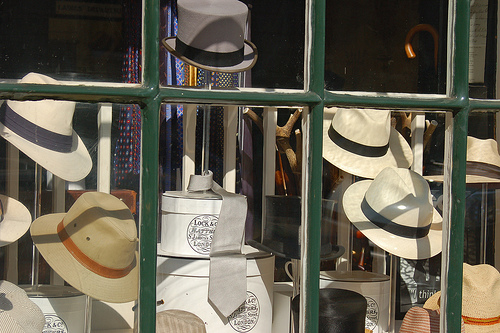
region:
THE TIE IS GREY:
[183, 162, 259, 318]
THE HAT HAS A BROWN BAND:
[20, 188, 165, 319]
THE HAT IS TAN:
[23, 183, 158, 315]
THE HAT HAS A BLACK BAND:
[337, 157, 444, 282]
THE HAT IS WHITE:
[332, 163, 447, 273]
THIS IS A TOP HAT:
[160, 2, 267, 74]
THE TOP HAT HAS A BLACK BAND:
[161, 0, 269, 81]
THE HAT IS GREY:
[161, 0, 262, 76]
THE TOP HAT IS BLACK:
[282, 281, 373, 331]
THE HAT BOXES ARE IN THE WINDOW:
[2, 186, 392, 331]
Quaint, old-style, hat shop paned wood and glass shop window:
[3, 0, 497, 330]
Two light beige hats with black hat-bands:
[323, 105, 442, 259]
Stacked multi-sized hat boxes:
[161, 188, 281, 332]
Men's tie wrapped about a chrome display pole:
[186, 168, 248, 320]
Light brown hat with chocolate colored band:
[28, 188, 140, 304]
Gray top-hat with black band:
[165, 0, 260, 73]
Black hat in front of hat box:
[320, 263, 392, 331]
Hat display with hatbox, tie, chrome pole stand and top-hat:
[163, 0, 261, 259]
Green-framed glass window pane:
[135, 84, 323, 331]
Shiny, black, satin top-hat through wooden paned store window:
[246, 190, 348, 266]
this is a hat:
[346, 162, 455, 232]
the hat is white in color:
[352, 182, 435, 234]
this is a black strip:
[331, 135, 373, 153]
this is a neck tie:
[203, 165, 247, 303]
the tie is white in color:
[223, 203, 245, 271]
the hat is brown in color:
[71, 200, 129, 248]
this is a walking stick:
[407, 19, 452, 66]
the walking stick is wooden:
[399, 23, 429, 55]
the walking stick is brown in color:
[400, 18, 427, 55]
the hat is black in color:
[322, 289, 364, 321]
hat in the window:
[324, 90, 412, 177]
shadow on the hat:
[343, 211, 393, 250]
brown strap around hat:
[68, 233, 111, 274]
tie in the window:
[191, 178, 260, 309]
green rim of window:
[110, 115, 182, 248]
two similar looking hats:
[325, 107, 450, 304]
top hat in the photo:
[163, 5, 276, 80]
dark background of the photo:
[335, 20, 402, 75]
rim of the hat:
[365, 231, 407, 264]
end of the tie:
[205, 289, 247, 330]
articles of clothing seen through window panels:
[2, 2, 498, 332]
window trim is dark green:
[1, 3, 498, 330]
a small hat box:
[161, 189, 246, 255]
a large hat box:
[158, 246, 273, 331]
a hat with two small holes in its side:
[30, 187, 140, 302]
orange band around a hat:
[434, 296, 499, 328]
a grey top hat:
[162, 0, 257, 70]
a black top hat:
[249, 192, 342, 262]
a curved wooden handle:
[400, 21, 440, 78]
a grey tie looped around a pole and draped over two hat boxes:
[160, 109, 267, 331]